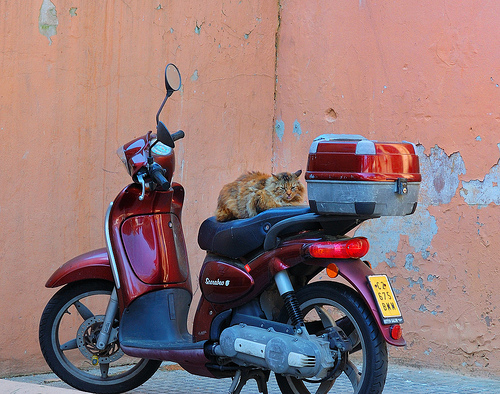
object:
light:
[309, 237, 370, 259]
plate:
[368, 275, 402, 318]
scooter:
[37, 63, 421, 394]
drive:
[213, 323, 335, 379]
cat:
[215, 169, 307, 222]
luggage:
[305, 133, 422, 216]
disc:
[76, 314, 125, 364]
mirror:
[166, 65, 180, 91]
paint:
[375, 146, 412, 174]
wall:
[0, 0, 499, 382]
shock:
[96, 286, 118, 351]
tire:
[39, 278, 163, 393]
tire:
[274, 280, 387, 393]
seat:
[198, 206, 311, 257]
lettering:
[205, 278, 231, 287]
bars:
[129, 123, 183, 206]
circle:
[391, 324, 402, 339]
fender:
[45, 247, 114, 288]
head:
[271, 169, 303, 201]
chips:
[459, 159, 499, 208]